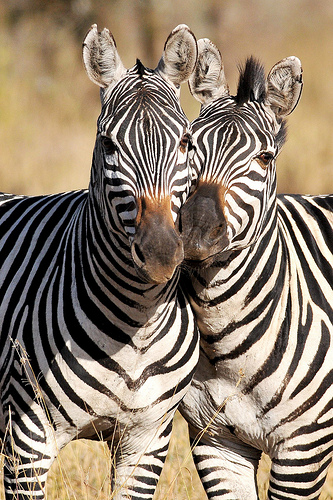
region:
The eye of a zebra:
[247, 136, 282, 172]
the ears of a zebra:
[76, 20, 202, 89]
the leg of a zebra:
[99, 413, 174, 498]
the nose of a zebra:
[114, 200, 195, 284]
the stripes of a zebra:
[14, 237, 121, 346]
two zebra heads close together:
[80, 67, 298, 282]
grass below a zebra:
[51, 405, 139, 489]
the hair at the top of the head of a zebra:
[226, 46, 268, 114]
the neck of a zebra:
[78, 207, 188, 360]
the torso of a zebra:
[206, 289, 323, 403]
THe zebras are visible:
[113, 275, 264, 372]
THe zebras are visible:
[83, 226, 289, 444]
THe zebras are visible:
[129, 314, 254, 434]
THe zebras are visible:
[63, 217, 319, 302]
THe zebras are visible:
[114, 297, 229, 397]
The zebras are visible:
[140, 315, 217, 389]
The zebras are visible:
[137, 378, 241, 425]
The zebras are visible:
[163, 344, 293, 400]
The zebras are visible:
[102, 300, 268, 385]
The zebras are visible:
[108, 313, 289, 442]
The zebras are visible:
[93, 261, 249, 422]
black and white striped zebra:
[178, 30, 331, 499]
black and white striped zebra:
[0, 11, 198, 498]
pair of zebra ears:
[68, 17, 197, 88]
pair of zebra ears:
[187, 30, 303, 117]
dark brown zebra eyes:
[98, 127, 188, 157]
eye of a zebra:
[250, 143, 280, 167]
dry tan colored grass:
[3, 332, 332, 496]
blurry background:
[4, 3, 331, 194]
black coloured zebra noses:
[121, 191, 231, 283]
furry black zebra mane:
[227, 55, 266, 106]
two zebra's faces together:
[63, 31, 330, 285]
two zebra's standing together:
[0, 67, 332, 498]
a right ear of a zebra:
[259, 54, 307, 120]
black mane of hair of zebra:
[219, 55, 269, 101]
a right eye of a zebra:
[249, 144, 279, 168]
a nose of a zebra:
[183, 175, 247, 239]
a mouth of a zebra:
[185, 252, 226, 264]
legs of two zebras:
[0, 425, 331, 495]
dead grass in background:
[47, 444, 331, 497]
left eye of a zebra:
[84, 134, 120, 161]